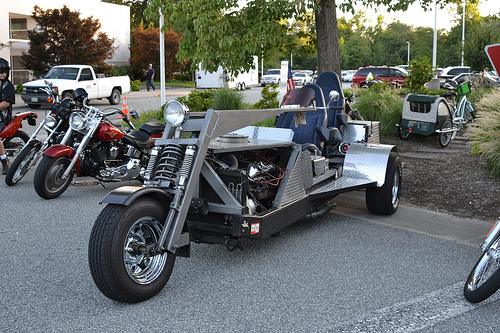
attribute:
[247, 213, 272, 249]
sticker — red, white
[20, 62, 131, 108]
truck — white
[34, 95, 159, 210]
motorcycle — red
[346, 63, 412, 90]
van — red, parked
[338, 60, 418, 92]
sticker — red, white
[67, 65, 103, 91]
sticker — red, white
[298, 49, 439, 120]
car — red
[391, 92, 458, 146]
holder — small